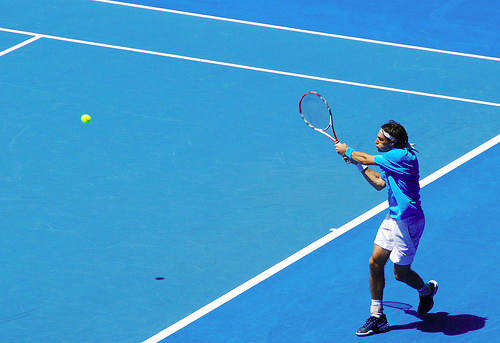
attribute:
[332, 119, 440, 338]
tennis player — concentrating, male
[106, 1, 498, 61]
line — white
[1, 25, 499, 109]
line — white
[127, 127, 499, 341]
line — white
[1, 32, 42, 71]
line — white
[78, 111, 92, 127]
tennis ball — yellow, flying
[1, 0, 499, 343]
court — light blue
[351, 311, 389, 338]
shoe — black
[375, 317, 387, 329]
nike emblem — blue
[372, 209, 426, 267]
shorts — white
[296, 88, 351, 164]
tennis racket — white, red, multicolored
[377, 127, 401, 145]
headband — white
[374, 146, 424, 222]
shirt — blue, turqouise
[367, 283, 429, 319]
socks — white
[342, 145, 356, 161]
sweat band — blue